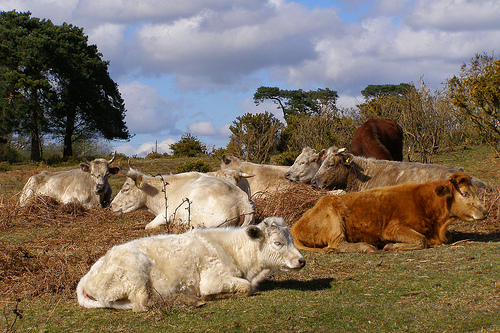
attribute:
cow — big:
[18, 149, 119, 213]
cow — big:
[320, 181, 491, 244]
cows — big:
[21, 158, 111, 210]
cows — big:
[111, 168, 256, 235]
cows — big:
[292, 173, 490, 252]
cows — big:
[77, 216, 304, 309]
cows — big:
[311, 146, 490, 218]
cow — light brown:
[267, 144, 485, 278]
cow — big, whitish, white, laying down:
[72, 216, 307, 312]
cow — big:
[311, 146, 498, 193]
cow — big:
[290, 170, 493, 255]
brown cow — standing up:
[336, 109, 416, 164]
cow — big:
[291, 166, 483, 256]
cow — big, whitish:
[106, 165, 258, 232]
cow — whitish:
[310, 144, 495, 196]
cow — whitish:
[208, 140, 305, 201]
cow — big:
[41, 165, 319, 332]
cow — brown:
[281, 167, 491, 259]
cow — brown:
[64, 212, 311, 317]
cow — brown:
[106, 165, 266, 236]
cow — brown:
[11, 147, 129, 215]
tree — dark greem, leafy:
[4, 5, 141, 195]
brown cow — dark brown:
[346, 116, 406, 159]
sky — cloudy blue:
[240, 24, 334, 68]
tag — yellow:
[246, 211, 262, 245]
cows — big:
[19, 118, 487, 313]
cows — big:
[33, 140, 464, 292]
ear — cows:
[242, 218, 274, 244]